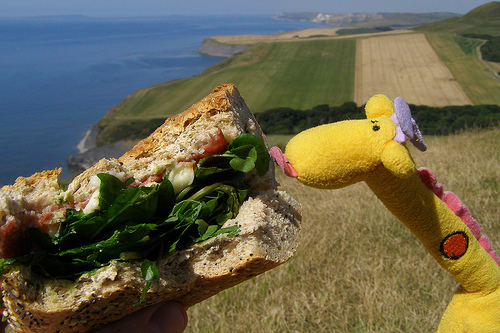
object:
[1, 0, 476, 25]
sky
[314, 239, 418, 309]
light grass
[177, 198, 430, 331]
field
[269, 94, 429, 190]
head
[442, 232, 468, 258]
red circle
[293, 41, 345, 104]
grass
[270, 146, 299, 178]
tongue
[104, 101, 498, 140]
trees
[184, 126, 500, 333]
grass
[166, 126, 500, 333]
ground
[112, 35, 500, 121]
short grass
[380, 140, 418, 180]
ears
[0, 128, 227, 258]
meat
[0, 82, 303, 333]
bread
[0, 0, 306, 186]
water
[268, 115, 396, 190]
face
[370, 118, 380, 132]
eyes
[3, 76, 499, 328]
forefront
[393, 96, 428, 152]
hat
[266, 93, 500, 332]
giraffe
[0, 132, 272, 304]
lettuce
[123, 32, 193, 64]
ledge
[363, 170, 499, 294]
neck